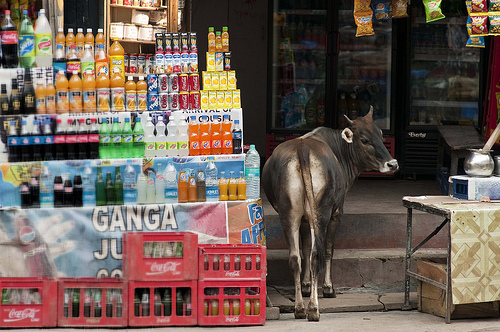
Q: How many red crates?
A: Six.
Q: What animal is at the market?
A: Ox.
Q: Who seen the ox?
A: No indication.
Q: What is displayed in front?
A: Drinks.